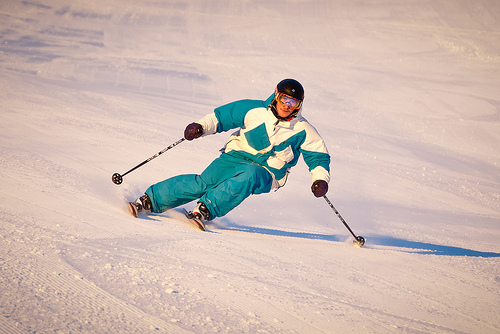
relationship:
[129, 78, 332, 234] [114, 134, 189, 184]
man holding poles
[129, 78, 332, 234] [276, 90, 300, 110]
man has goggles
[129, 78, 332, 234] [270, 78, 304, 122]
man has hat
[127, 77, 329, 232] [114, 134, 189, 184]
woman has poles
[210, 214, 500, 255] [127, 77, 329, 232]
shadow of woman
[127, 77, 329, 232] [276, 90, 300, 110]
woman wears goggles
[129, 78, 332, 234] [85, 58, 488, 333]
man at slope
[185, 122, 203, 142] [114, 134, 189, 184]
gloves at poles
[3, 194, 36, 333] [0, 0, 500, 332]
edges of ground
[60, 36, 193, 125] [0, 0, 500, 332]
loops of ground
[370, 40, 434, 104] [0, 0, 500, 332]
pieces of ground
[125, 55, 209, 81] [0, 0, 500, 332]
mark at ground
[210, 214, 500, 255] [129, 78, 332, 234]
shadow at man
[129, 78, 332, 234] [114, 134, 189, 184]
man has poles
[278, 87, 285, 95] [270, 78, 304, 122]
part of hat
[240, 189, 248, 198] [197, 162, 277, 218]
edges of leg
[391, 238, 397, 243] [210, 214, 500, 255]
part of shadow